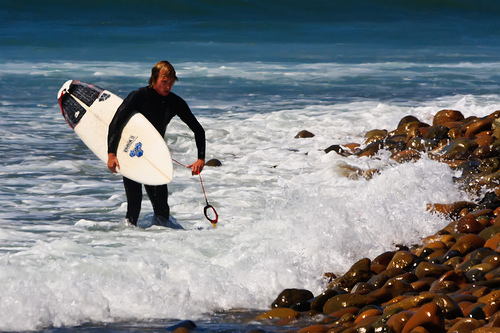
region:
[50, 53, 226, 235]
A man is holding a surfboard.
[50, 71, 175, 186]
The surfboard's colors are white, blue, black, and red.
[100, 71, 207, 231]
A man is wearing a wet suit.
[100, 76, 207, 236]
A wet suit's color is black.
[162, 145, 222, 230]
A handle is attached to a surfboard.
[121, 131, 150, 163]
A logo is on a surfboard.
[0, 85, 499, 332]
Foam is washing up on a shore.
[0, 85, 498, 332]
The foam's color is white.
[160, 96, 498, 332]
Rocks are on a shore.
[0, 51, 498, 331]
The sun is shining on a shoreline.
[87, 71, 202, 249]
Man holding surfboard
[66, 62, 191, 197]
Surfboard is white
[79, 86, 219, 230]
Man standing in water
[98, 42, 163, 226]
Man wearing wetsuit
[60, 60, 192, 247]
Man's wet suit is black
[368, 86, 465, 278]
Many rocks in and next to water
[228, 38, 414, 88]
Water is blue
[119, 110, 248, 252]
Black and red strap on surfboard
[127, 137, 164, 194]
Blue logo on bottom of surfboard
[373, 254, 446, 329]
Rocks are shades of brown and black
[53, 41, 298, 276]
the surfer is holding a surfboard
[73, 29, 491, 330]
There are rocks near the water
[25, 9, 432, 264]
The water is blue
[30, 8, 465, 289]
The photo was taken in the daytime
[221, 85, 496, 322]
Waves are hitting the rocks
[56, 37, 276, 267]
The surfer is wearing a wetsuit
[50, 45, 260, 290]
The surfer is wearing a black wetsuit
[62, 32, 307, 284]
The surfer is leaving the water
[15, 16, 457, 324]
The surfer is walking into the waves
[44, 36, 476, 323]
The surfer is walking towards the rocks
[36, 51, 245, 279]
A man holding a surf board.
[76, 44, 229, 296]
A man wearing a black wet suit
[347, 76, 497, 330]
The rocks on the beach.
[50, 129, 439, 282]
The white colored water on the beach.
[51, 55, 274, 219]
A man who is walking to shore.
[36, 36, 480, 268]
The blue water in the ocean.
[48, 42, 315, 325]
A man holding a white surf board.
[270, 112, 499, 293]
Waves hitting the shore rocks.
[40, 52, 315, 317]
A man walking in the water.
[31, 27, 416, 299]
A photo taken during the day.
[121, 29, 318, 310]
The surfer has a string in his hand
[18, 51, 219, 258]
The surfer is holding a surfboard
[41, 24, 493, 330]
The rocks are wet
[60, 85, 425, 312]
There are waves in the photo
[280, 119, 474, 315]
The rocks look brown wet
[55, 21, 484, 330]
The photo was taken during the daytime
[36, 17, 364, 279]
The man is wearing a black wetsuit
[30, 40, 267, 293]
The surfboard is mostly white